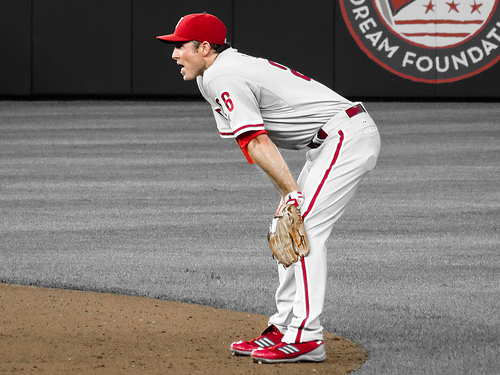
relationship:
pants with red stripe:
[266, 101, 383, 345] [315, 135, 343, 205]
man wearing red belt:
[154, 9, 383, 363] [342, 106, 364, 117]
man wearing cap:
[154, 9, 383, 363] [155, 11, 229, 48]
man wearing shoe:
[154, 9, 383, 363] [225, 323, 283, 354]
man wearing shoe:
[154, 9, 383, 363] [249, 336, 322, 366]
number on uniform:
[221, 90, 237, 111] [189, 47, 383, 343]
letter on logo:
[398, 49, 416, 69] [333, 0, 499, 83]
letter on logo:
[414, 53, 434, 71] [333, 0, 499, 83]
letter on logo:
[435, 56, 449, 72] [333, 0, 499, 83]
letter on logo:
[464, 44, 485, 64] [333, 0, 499, 83]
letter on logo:
[376, 39, 397, 59] [333, 0, 499, 83]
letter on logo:
[365, 26, 383, 48] [333, 0, 499, 83]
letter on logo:
[357, 16, 377, 31] [333, 0, 499, 83]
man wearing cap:
[154, 9, 384, 359] [155, 11, 229, 48]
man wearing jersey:
[154, 9, 384, 359] [193, 44, 358, 151]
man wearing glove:
[154, 9, 384, 359] [266, 190, 310, 267]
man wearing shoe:
[154, 9, 384, 359] [250, 333, 329, 365]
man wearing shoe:
[154, 9, 384, 359] [229, 325, 285, 357]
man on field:
[154, 9, 384, 359] [2, 98, 498, 372]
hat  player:
[211, 114, 245, 137] [142, 60, 446, 366]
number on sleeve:
[216, 90, 236, 111] [192, 101, 270, 151]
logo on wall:
[353, 60, 495, 94] [7, 99, 494, 205]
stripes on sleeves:
[206, 122, 266, 142] [205, 123, 265, 154]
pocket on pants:
[351, 113, 377, 141] [250, 110, 425, 350]